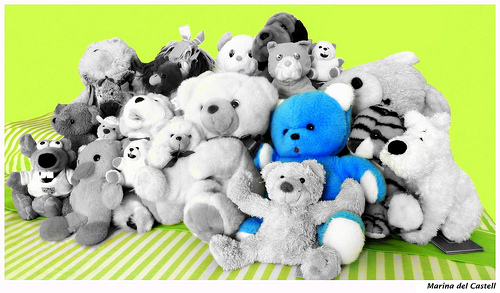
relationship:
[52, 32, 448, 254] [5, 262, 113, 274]
animals on a bed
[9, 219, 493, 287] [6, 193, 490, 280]
stripes on floor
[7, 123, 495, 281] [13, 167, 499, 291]
stripes on floor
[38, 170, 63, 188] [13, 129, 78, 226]
big teeth of stuffed animal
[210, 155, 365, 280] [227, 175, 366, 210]
bear has hands